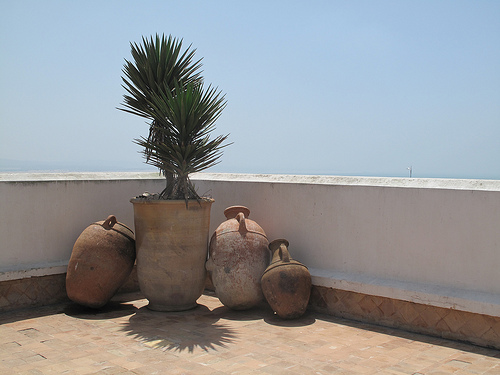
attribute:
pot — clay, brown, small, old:
[263, 238, 315, 319]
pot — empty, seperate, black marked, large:
[64, 216, 138, 309]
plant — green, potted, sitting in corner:
[116, 33, 232, 200]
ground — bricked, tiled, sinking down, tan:
[2, 283, 500, 373]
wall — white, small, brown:
[2, 167, 499, 317]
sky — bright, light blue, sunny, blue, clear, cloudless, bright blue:
[2, 2, 499, 176]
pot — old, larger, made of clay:
[205, 203, 274, 309]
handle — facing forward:
[100, 214, 117, 230]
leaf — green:
[126, 59, 151, 99]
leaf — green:
[126, 97, 149, 119]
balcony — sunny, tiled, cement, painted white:
[0, 167, 499, 374]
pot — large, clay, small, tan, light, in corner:
[128, 192, 211, 310]